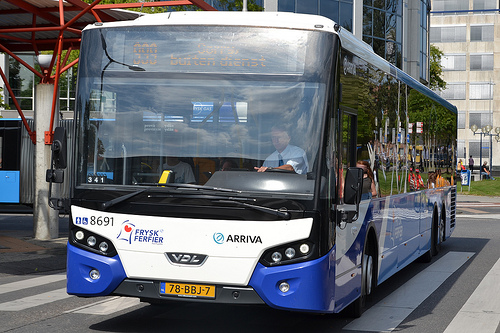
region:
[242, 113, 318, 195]
A driver on the bus.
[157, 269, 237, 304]
The tag plate on front of the bus.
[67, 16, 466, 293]
A bus is on the road.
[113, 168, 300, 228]
The wipers on the bus.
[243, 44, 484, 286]
The bus is blue and white.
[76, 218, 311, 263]
The headlights on the bus.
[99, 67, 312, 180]
The front windshield on the bus.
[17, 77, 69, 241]
A white pole on the walkway.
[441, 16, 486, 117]
Windows on the building.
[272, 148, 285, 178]
The driver is wearing a tie.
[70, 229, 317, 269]
Head lights of a bus driving down the street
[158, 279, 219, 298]
Yellow license plate on a bus 78-BBJ-7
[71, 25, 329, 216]
Front windshield of a bus driving down a street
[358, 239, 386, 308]
Front wheel of a bus driving down a street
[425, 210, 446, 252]
Rear wheel of a bus driving down a street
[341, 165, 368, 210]
Left mirror of a bus driving down a street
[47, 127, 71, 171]
Right mirror of a bus driving down a street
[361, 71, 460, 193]
Side windows of a bus driving down a street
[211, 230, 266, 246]
ARRIVA logo displayed on a bus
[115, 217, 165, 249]
FRYSK FERFIER logo on a bus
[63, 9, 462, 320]
a blue and white bus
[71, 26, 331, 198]
the front window of a bus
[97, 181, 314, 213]
windshield wipers on the front window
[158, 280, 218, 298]
the front license plate on the bus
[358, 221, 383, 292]
the front wheelwell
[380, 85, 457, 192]
the side windows of the bus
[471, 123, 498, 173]
a large lampost with multiple globes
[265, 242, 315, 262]
three lights on the front of the bus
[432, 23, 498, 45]
a row of windows in a building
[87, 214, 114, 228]
the number 8691 displayed on the front of a bus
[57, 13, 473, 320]
bus on the street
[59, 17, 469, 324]
blue and white bus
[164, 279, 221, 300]
yellow and black license plate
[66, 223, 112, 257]
row of three lights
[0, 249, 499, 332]
white lines of the crosswalk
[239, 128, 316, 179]
bus driver sitting behind the wheel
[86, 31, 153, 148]
reflection on windshield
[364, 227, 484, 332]
shadow on the ground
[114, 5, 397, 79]
roof of the bus is white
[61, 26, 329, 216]
large windshield on the front of the bus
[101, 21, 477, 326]
the bus has people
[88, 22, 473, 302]
one can see inside the bus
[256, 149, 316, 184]
the driver has white shirt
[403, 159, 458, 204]
reflection is on the side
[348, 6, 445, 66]
building is in the background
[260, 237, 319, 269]
the lights are circular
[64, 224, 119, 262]
the lights are round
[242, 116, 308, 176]
the man has a tie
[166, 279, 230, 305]
the license plate is yellow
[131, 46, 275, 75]
the distination is illuminated